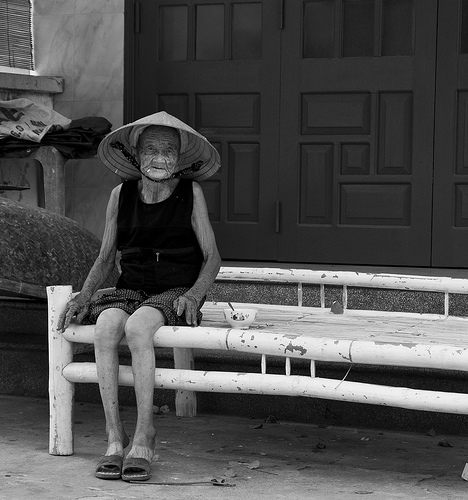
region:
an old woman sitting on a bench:
[36, 85, 267, 495]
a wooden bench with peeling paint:
[252, 266, 457, 420]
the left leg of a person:
[130, 323, 160, 433]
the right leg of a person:
[93, 333, 123, 431]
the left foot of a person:
[125, 437, 158, 459]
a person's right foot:
[103, 429, 126, 455]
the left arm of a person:
[188, 199, 220, 290]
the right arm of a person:
[82, 202, 113, 284]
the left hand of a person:
[171, 289, 195, 319]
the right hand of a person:
[53, 290, 85, 333]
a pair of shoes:
[95, 452, 154, 482]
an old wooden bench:
[39, 260, 466, 457]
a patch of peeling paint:
[276, 333, 308, 355]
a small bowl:
[220, 300, 257, 328]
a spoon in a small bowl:
[221, 301, 256, 325]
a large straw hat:
[96, 108, 220, 177]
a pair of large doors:
[116, 0, 467, 266]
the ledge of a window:
[0, 70, 67, 94]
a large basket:
[0, 193, 108, 298]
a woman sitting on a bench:
[37, 109, 269, 471]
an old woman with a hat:
[66, 85, 266, 474]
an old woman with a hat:
[64, 93, 231, 329]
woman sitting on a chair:
[26, 71, 237, 496]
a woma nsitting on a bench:
[88, 105, 432, 401]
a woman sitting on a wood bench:
[60, 121, 386, 421]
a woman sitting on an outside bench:
[51, 111, 385, 480]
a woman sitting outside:
[30, 99, 338, 478]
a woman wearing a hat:
[72, 87, 240, 244]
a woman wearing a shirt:
[90, 81, 282, 328]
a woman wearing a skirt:
[80, 104, 328, 405]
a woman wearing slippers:
[57, 93, 151, 488]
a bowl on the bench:
[203, 269, 303, 388]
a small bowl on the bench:
[215, 277, 459, 420]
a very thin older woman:
[54, 105, 229, 478]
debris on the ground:
[210, 441, 282, 494]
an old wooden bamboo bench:
[185, 266, 454, 427]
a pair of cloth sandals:
[95, 449, 157, 487]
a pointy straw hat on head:
[112, 109, 216, 139]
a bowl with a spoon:
[219, 294, 270, 330]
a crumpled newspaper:
[3, 95, 59, 139]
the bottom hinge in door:
[271, 200, 288, 234]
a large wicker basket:
[6, 203, 88, 293]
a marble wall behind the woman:
[46, 10, 120, 91]